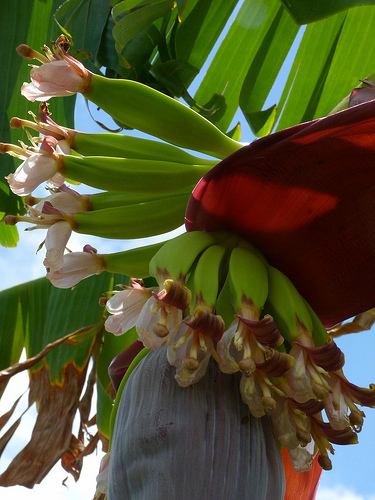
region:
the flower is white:
[61, 267, 290, 409]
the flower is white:
[105, 281, 260, 481]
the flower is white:
[20, 228, 215, 397]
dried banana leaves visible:
[15, 355, 87, 477]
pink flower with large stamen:
[3, 26, 93, 106]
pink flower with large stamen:
[0, 100, 83, 147]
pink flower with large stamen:
[0, 128, 69, 201]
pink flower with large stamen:
[0, 163, 96, 260]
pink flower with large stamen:
[30, 235, 108, 291]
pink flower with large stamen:
[95, 269, 149, 341]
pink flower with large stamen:
[130, 267, 187, 354]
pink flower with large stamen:
[156, 304, 224, 397]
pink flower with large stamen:
[203, 302, 283, 380]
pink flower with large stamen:
[273, 326, 347, 414]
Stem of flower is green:
[86, 60, 241, 161]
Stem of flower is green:
[53, 144, 220, 195]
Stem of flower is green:
[61, 189, 203, 239]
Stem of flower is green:
[267, 259, 317, 342]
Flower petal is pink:
[30, 54, 86, 94]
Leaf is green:
[239, 1, 296, 143]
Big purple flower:
[109, 348, 286, 498]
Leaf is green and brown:
[0, 265, 140, 490]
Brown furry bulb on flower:
[15, 44, 35, 58]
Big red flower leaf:
[180, 97, 374, 334]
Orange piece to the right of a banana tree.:
[278, 439, 325, 499]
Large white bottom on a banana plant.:
[100, 346, 286, 499]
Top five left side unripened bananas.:
[71, 70, 244, 238]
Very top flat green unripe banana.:
[79, 70, 248, 163]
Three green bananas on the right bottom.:
[229, 243, 331, 354]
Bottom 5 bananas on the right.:
[146, 228, 331, 351]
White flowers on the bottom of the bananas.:
[104, 286, 370, 468]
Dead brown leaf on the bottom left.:
[0, 368, 85, 487]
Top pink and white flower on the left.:
[19, 54, 85, 102]